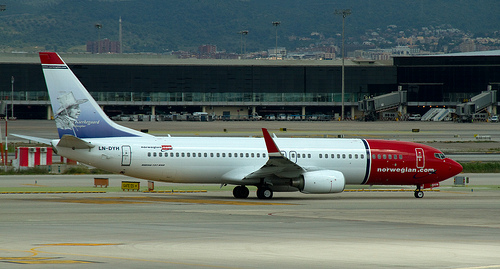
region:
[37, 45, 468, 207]
red and white plane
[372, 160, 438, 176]
norwegian.com logo on plane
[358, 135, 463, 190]
red front of plane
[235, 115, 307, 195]
white wing with red tip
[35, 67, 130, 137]
portrait of woman on tip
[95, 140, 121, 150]
black letters next to door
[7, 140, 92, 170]
red and white barrier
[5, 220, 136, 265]
yellow lines on concrete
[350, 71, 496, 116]
terminal gates in right background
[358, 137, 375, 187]
black stripe between red and white sections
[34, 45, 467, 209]
long red and white plane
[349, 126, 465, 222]
deep red nose of a plane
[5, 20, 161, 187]
red blue and white plane tail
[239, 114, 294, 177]
red wing tip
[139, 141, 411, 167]
row of windows on a plane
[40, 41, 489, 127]
short airport building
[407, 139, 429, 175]
white bordered airplane door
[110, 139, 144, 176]
door of an airplane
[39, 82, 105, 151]
image of a man in a hat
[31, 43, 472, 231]
air plane sitting on a runway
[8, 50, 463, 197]
airplane is parked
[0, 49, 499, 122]
airport behind airplane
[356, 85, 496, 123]
two jetways behind airplane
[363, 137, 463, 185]
front of airplane is red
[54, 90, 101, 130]
image on airplane tail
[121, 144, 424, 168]
four doors on airplane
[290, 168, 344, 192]
engine on wing of airplane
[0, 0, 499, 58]
green hill behind airport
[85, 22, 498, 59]
city behind the airport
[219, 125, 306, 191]
wing is angled up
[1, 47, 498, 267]
The airplane is on the runway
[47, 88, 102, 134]
Cowboy painted on tail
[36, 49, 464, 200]
plane is red, white, and blue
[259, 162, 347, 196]
plane engine is turbine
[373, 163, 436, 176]
norwegian.com is wrote on side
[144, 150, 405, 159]
small windows on plane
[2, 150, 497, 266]
runway is paved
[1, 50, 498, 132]
airport terminal is behind plane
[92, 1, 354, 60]
several large light poles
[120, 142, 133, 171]
small white door on plane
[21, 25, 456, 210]
an airplane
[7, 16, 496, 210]
This is an airport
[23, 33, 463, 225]
Red, blue, and white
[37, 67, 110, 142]
A man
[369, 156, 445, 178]
"Nerwglan.com"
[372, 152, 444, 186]
The text is white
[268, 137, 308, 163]
The plane's doors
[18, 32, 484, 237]
This plane is parked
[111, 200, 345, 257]
The street is grey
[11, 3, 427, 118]
It is not sunny at the airport